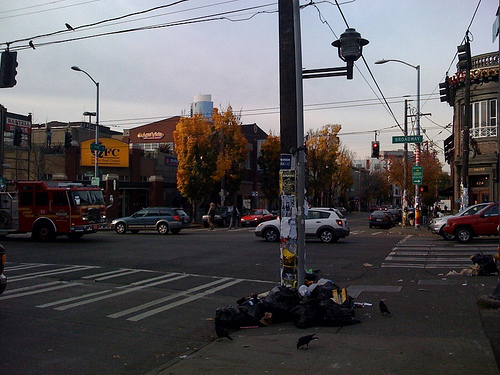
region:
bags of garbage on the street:
[219, 266, 364, 329]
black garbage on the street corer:
[218, 278, 349, 327]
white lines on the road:
[33, 248, 219, 318]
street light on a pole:
[309, 23, 375, 82]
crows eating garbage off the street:
[214, 289, 319, 368]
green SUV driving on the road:
[125, 201, 189, 236]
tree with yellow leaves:
[174, 103, 256, 186]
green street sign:
[381, 127, 433, 146]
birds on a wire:
[21, 20, 91, 56]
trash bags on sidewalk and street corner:
[208, 270, 365, 338]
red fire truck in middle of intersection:
[0, 168, 121, 245]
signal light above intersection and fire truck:
[0, 44, 26, 91]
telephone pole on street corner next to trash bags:
[268, 0, 313, 291]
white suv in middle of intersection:
[249, 197, 349, 249]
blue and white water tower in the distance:
[186, 78, 224, 128]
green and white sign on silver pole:
[406, 158, 426, 195]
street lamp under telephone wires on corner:
[327, 20, 369, 84]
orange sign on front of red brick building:
[74, 130, 134, 175]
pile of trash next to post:
[207, 269, 362, 351]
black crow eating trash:
[286, 327, 317, 354]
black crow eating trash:
[375, 298, 396, 325]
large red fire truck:
[0, 175, 122, 233]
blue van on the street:
[106, 195, 191, 241]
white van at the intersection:
[248, 193, 349, 243]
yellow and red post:
[73, 135, 130, 170]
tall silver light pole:
[67, 60, 109, 183]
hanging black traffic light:
[0, 37, 30, 103]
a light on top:
[307, 18, 392, 85]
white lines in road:
[6, 247, 223, 326]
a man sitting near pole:
[287, 252, 387, 342]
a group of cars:
[83, 188, 463, 269]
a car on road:
[109, 191, 184, 250]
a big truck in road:
[16, 183, 94, 250]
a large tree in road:
[156, 105, 274, 229]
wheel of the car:
[318, 228, 338, 254]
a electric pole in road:
[248, 23, 340, 334]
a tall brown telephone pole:
[264, 9, 321, 280]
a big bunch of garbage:
[245, 276, 342, 326]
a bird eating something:
[290, 323, 320, 353]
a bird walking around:
[370, 290, 392, 316]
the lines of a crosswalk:
[47, 242, 197, 342]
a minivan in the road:
[103, 178, 184, 241]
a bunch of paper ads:
[275, 165, 296, 255]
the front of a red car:
[450, 203, 495, 245]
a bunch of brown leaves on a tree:
[167, 118, 237, 195]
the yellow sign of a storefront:
[85, 127, 125, 169]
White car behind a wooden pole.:
[255, 207, 349, 245]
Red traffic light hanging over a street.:
[368, 132, 381, 159]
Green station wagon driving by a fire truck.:
[109, 206, 194, 234]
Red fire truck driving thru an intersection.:
[1, 176, 108, 244]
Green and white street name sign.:
[391, 135, 422, 143]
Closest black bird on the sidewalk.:
[294, 331, 319, 351]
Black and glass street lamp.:
[304, 26, 368, 81]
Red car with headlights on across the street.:
[240, 207, 276, 229]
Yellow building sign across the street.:
[81, 136, 129, 166]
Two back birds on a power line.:
[27, 20, 80, 53]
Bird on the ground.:
[366, 286, 398, 326]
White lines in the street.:
[38, 247, 193, 334]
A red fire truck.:
[0, 182, 121, 248]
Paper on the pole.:
[273, 153, 300, 258]